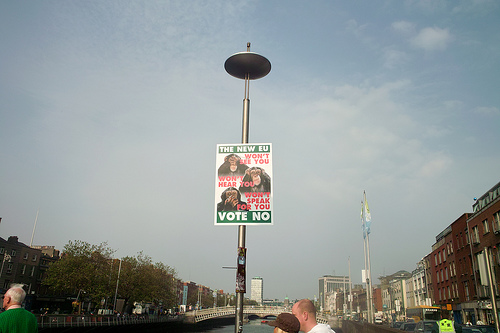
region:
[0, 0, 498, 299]
The sky is blue.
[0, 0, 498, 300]
The sky is clear.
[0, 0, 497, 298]
The sky has a few clouds in it.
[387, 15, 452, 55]
The clouds are white.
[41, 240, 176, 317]
The trees are green.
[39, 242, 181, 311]
The trees have leaves on them.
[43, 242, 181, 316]
Trees are in the background.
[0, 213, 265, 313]
A row of buildings.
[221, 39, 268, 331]
A street light.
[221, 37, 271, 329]
The street light is made of metal.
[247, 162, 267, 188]
Monkey on a poster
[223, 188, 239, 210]
Monkey on a poster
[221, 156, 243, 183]
Monkey on a poster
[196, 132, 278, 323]
A sign board on the street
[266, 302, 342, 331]
Heads of two men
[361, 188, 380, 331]
Sign board outside building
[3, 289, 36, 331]
A man in green sweater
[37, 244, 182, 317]
A tree growing on the street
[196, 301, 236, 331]
A metallic white bridge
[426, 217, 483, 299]
A brown beautiful tall building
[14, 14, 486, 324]
a city scene with a sign in the middle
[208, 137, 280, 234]
a sign with monkeys on it saying "VOTE NO"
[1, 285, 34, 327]
older man with a green sweater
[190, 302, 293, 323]
white bridge over a river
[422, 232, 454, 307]
old red building with windows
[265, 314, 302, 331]
woman wearing a brown hat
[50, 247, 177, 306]
trees with green leaves lining the street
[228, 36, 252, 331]
large metal pole with a round top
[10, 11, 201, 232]
hazy blue sky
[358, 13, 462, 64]
small white clouds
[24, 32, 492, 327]
A sign in the middle of a city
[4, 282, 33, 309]
The man is balding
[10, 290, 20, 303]
The man has white hair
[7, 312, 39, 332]
A green sweater on the man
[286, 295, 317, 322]
The man has a receding hairline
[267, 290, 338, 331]
A couple walking under the sign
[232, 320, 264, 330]
The water is calm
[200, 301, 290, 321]
A small bridge in the distance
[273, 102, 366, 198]
Thick white clouds in the sky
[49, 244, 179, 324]
Trees near the bridge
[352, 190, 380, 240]
Two flags on metal flagpoles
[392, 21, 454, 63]
A wispy white cloud in the sky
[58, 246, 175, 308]
Green trees near the bridge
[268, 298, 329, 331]
A married couple walking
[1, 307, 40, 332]
Green sweater on the man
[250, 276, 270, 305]
A skyscraper behind the bridge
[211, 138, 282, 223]
A sign urging people to vote no on the new EU